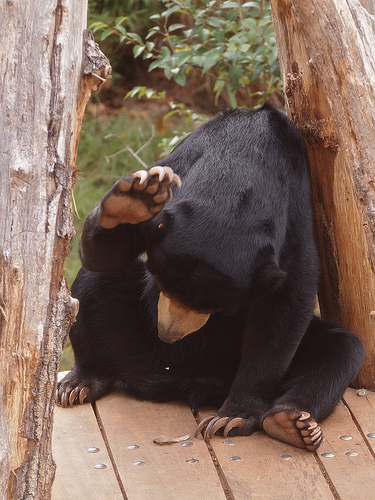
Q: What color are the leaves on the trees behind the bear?
A: Green.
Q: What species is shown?
A: A bear.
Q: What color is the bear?
A: Black.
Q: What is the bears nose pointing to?
A: The floor.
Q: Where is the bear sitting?
A: Wooden platform.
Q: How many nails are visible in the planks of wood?
A: Fifteen.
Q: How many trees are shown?
A: Two.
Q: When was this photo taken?
A: Day time.